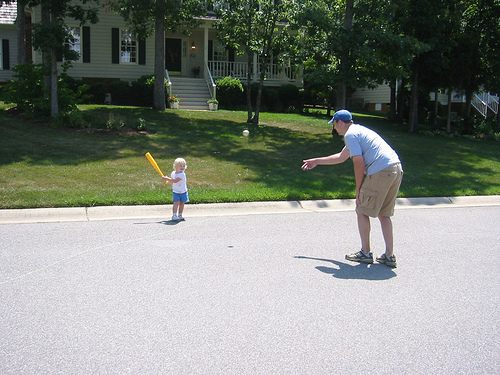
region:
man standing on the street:
[296, 98, 411, 283]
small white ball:
[241, 123, 253, 139]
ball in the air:
[240, 128, 250, 138]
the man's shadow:
[296, 246, 398, 284]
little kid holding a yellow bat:
[141, 144, 203, 223]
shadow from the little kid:
[135, 215, 188, 228]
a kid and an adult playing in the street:
[111, 104, 432, 286]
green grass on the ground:
[2, 98, 497, 205]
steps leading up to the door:
[163, 39, 215, 116]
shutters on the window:
[109, 23, 147, 71]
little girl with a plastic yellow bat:
[132, 135, 195, 220]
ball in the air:
[233, 112, 252, 142]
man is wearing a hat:
[320, 103, 347, 133]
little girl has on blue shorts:
[172, 185, 187, 202]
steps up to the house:
[164, 60, 221, 112]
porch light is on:
[190, 34, 196, 54]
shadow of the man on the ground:
[289, 250, 394, 290]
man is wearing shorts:
[362, 171, 407, 223]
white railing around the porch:
[203, 54, 300, 83]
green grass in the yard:
[401, 133, 470, 184]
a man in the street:
[293, 106, 410, 280]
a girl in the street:
[138, 141, 202, 239]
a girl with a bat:
[137, 140, 202, 230]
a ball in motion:
[237, 123, 257, 146]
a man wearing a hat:
[287, 100, 420, 293]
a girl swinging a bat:
[141, 140, 201, 241]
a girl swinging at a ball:
[136, 103, 262, 240]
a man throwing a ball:
[234, 69, 425, 292]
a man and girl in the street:
[131, 90, 423, 277]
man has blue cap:
[329, 105, 363, 134]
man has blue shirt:
[350, 116, 382, 183]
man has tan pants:
[360, 173, 397, 214]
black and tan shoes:
[325, 245, 421, 283]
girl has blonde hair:
[174, 161, 183, 168]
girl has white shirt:
[163, 169, 183, 194]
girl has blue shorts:
[165, 194, 190, 203]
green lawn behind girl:
[115, 116, 306, 205]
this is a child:
[160, 159, 187, 220]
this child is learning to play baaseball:
[139, 146, 200, 226]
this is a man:
[326, 110, 415, 272]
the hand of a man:
[303, 148, 335, 173]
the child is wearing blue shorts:
[166, 193, 194, 207]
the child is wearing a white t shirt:
[174, 169, 185, 196]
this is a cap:
[327, 103, 354, 118]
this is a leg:
[342, 215, 375, 265]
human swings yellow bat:
[141, 146, 193, 223]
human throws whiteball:
[297, 107, 404, 274]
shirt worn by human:
[339, 122, 399, 177]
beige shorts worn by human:
[351, 161, 402, 216]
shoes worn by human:
[344, 245, 376, 265]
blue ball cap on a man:
[325, 108, 355, 127]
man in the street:
[296, 108, 405, 273]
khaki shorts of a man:
[356, 160, 402, 220]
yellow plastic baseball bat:
[145, 145, 168, 184]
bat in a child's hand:
[143, 147, 171, 185]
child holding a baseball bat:
[166, 157, 191, 220]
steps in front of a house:
[166, 66, 216, 111]